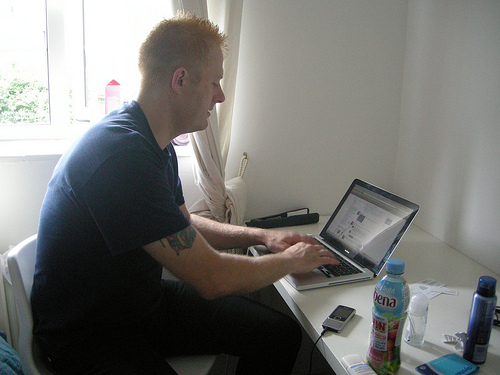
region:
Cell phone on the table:
[320, 301, 357, 333]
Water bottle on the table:
[364, 256, 412, 374]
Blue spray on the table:
[460, 273, 498, 363]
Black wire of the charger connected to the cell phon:
[305, 328, 332, 374]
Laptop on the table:
[250, 174, 422, 291]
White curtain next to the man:
[170, 0, 250, 255]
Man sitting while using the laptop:
[29, 11, 341, 374]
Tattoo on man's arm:
[160, 224, 201, 256]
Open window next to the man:
[2, 1, 171, 142]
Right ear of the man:
[167, 66, 189, 93]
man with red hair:
[122, 18, 237, 168]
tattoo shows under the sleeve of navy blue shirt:
[35, 100, 192, 372]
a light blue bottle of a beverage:
[363, 258, 413, 373]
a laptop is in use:
[246, 176, 416, 288]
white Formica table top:
[250, 191, 496, 371]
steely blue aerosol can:
[460, 264, 496, 371]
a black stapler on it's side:
[242, 191, 322, 229]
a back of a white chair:
[0, 221, 36, 371]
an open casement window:
[60, 0, 130, 125]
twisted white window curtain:
[162, 0, 244, 235]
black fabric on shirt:
[106, 319, 121, 325]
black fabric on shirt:
[61, 320, 81, 322]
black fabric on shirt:
[111, 283, 126, 295]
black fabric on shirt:
[48, 280, 58, 287]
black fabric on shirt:
[146, 195, 151, 211]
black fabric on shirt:
[58, 193, 60, 196]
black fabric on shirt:
[146, 161, 152, 164]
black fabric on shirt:
[171, 169, 181, 189]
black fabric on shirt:
[63, 201, 103, 331]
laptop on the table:
[275, 163, 392, 296]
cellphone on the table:
[327, 300, 354, 338]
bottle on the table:
[372, 258, 407, 372]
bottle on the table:
[463, 272, 483, 364]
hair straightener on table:
[245, 204, 318, 228]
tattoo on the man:
[158, 226, 200, 261]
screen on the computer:
[321, 179, 400, 256]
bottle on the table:
[404, 291, 433, 356]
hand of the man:
[285, 235, 332, 274]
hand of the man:
[275, 225, 303, 248]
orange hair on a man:
[137, 11, 231, 89]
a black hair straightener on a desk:
[242, 200, 322, 230]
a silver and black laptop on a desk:
[261, 175, 420, 293]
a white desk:
[247, 205, 498, 373]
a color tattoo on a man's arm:
[156, 219, 200, 257]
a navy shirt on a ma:
[26, 97, 186, 331]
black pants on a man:
[26, 281, 302, 374]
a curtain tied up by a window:
[170, 0, 251, 230]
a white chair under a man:
[6, 230, 223, 373]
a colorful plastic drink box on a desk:
[365, 251, 412, 373]